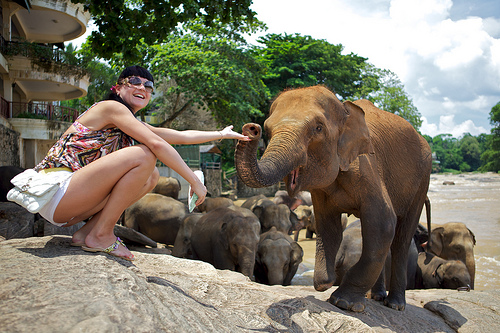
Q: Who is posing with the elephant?
A: Female tourist.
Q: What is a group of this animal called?
A: Herd.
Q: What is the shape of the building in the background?
A: Circular.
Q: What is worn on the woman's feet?
A: Flip flops.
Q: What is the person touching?
A: An elephant.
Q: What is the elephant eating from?
A: The person's hand.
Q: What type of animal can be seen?
A: Elephants.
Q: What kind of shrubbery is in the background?
A: Trees.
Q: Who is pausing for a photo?
A: A lady.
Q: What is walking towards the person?
A: A lady.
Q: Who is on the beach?
A: A woman.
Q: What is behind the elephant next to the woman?
A: A group of elephants.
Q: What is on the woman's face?
A: Glasses.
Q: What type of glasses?
A: Sunglasses.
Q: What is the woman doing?
A: Touching the elephant's trunk.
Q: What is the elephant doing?
A: Smiling.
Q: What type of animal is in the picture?
A: Elephant.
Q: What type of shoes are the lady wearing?
A: Sandals.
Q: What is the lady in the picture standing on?
A: A rock.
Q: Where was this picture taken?
A: Zoo.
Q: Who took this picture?
A: Her husband.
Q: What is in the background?
A: Trees.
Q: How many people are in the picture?
A: One.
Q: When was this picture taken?
A: Last month.